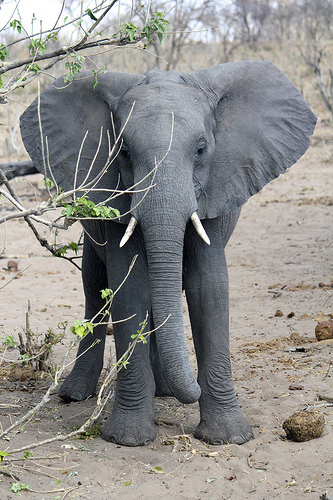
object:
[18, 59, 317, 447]
elephant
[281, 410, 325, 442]
poop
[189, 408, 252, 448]
feet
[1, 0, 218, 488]
tree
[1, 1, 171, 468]
leaves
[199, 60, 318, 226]
ears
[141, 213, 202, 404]
trunk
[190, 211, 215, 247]
tusk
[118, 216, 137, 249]
tusk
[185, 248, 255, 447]
leg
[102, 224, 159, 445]
leg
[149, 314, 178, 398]
leg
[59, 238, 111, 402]
leg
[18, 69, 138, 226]
ear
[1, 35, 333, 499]
ground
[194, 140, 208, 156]
eye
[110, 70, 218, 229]
head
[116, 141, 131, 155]
eye